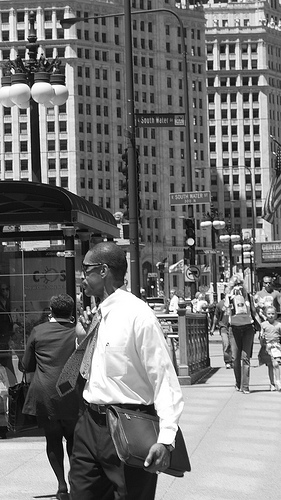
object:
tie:
[56, 311, 103, 399]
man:
[56, 240, 192, 500]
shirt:
[74, 283, 184, 451]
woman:
[222, 274, 262, 393]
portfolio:
[106, 403, 191, 478]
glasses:
[81, 261, 105, 273]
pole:
[26, 10, 42, 183]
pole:
[124, 0, 142, 308]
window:
[0, 251, 66, 384]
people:
[257, 305, 280, 392]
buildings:
[0, 0, 281, 315]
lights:
[0, 59, 16, 107]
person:
[18, 291, 78, 499]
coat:
[18, 320, 87, 422]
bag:
[228, 288, 246, 317]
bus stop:
[0, 180, 122, 439]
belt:
[81, 398, 155, 418]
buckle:
[96, 403, 107, 415]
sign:
[182, 265, 202, 288]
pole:
[178, 13, 196, 312]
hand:
[143, 441, 170, 474]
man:
[251, 274, 280, 325]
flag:
[261, 168, 281, 224]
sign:
[134, 112, 186, 127]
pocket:
[105, 341, 127, 375]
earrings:
[47, 313, 53, 322]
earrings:
[69, 315, 76, 323]